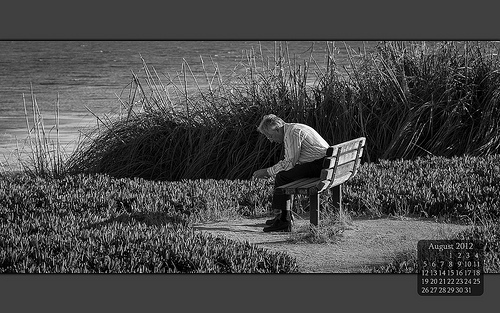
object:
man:
[249, 112, 334, 233]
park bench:
[274, 133, 371, 237]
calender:
[414, 236, 488, 299]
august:
[424, 241, 455, 253]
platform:
[190, 201, 492, 273]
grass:
[3, 154, 500, 272]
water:
[0, 39, 499, 173]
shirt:
[266, 120, 332, 177]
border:
[0, 37, 499, 275]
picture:
[2, 1, 498, 310]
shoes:
[262, 216, 295, 232]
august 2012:
[423, 241, 479, 253]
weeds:
[288, 200, 356, 246]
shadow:
[75, 191, 266, 246]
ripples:
[31, 73, 113, 90]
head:
[255, 109, 286, 148]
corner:
[390, 234, 500, 311]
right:
[360, 0, 500, 312]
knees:
[272, 167, 295, 193]